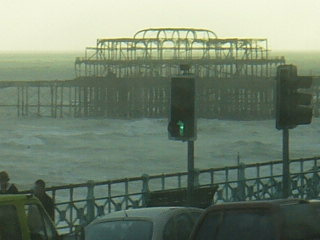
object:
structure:
[67, 32, 285, 94]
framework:
[76, 31, 174, 74]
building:
[79, 33, 283, 118]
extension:
[9, 55, 73, 113]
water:
[11, 53, 59, 78]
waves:
[15, 125, 28, 135]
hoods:
[122, 183, 245, 203]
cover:
[295, 74, 312, 88]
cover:
[293, 91, 312, 107]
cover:
[295, 106, 311, 129]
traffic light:
[273, 61, 314, 129]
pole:
[281, 127, 292, 199]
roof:
[86, 205, 205, 224]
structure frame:
[65, 76, 118, 119]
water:
[0, 113, 139, 167]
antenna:
[121, 206, 129, 218]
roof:
[0, 191, 40, 206]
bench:
[142, 182, 218, 205]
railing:
[0, 153, 318, 239]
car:
[66, 203, 209, 239]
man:
[25, 177, 55, 230]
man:
[0, 171, 17, 196]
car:
[186, 198, 319, 239]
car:
[70, 206, 208, 239]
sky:
[4, 3, 319, 47]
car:
[1, 187, 66, 238]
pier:
[6, 72, 319, 119]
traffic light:
[164, 71, 203, 145]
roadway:
[70, 188, 317, 238]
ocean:
[0, 39, 320, 211]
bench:
[140, 181, 223, 205]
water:
[297, 131, 314, 156]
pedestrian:
[28, 174, 60, 219]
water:
[195, 115, 260, 162]